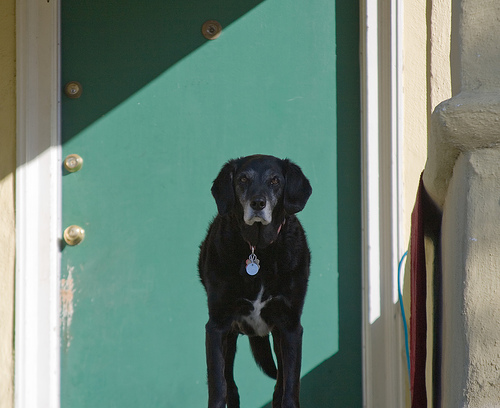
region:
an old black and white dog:
[182, 143, 340, 406]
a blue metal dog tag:
[236, 225, 272, 288]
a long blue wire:
[388, 233, 433, 406]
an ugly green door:
[58, 58, 174, 406]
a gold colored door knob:
[57, 216, 91, 261]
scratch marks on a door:
[49, 258, 88, 355]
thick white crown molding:
[11, 58, 72, 407]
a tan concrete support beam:
[415, 61, 499, 317]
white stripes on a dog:
[231, 275, 279, 343]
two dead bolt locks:
[59, 74, 91, 191]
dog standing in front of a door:
[175, 150, 342, 407]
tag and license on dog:
[242, 248, 262, 277]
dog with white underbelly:
[174, 146, 326, 406]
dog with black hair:
[181, 151, 325, 406]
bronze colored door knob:
[62, 218, 89, 253]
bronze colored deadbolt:
[59, 151, 85, 180]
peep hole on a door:
[199, 14, 223, 44]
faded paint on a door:
[53, 258, 78, 355]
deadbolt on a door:
[62, 78, 84, 101]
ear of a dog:
[281, 155, 316, 213]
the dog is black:
[162, 124, 314, 395]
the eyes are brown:
[222, 157, 305, 217]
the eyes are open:
[222, 155, 294, 192]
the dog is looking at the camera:
[180, 126, 312, 242]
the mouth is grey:
[235, 205, 273, 227]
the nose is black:
[242, 194, 268, 211]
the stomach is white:
[223, 283, 277, 362]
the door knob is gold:
[53, 203, 93, 259]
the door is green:
[25, 8, 334, 342]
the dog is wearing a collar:
[212, 219, 294, 276]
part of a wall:
[186, 63, 259, 150]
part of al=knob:
[48, 202, 101, 284]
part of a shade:
[313, 358, 348, 394]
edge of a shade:
[287, 332, 332, 376]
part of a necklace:
[238, 250, 263, 263]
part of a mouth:
[238, 203, 266, 260]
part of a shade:
[316, 335, 357, 377]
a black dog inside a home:
[175, 139, 327, 402]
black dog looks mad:
[183, 141, 325, 286]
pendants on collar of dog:
[235, 237, 275, 284]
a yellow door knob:
[52, 214, 94, 254]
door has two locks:
[53, 72, 100, 187]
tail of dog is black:
[245, 334, 283, 384]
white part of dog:
[237, 290, 277, 346]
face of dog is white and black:
[226, 144, 291, 237]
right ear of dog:
[279, 155, 321, 220]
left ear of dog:
[204, 152, 243, 222]